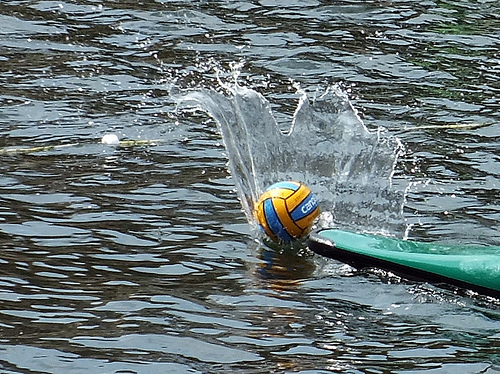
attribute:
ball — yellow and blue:
[253, 181, 318, 246]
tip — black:
[292, 203, 359, 274]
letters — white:
[296, 195, 320, 217]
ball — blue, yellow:
[252, 174, 318, 243]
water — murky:
[52, 77, 213, 345]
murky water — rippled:
[0, 0, 228, 371]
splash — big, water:
[167, 67, 406, 242]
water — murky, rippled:
[58, 260, 195, 342]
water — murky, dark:
[3, 6, 490, 372]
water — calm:
[88, 82, 217, 322]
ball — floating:
[247, 176, 329, 246]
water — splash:
[54, 30, 427, 353]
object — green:
[306, 212, 497, 298]